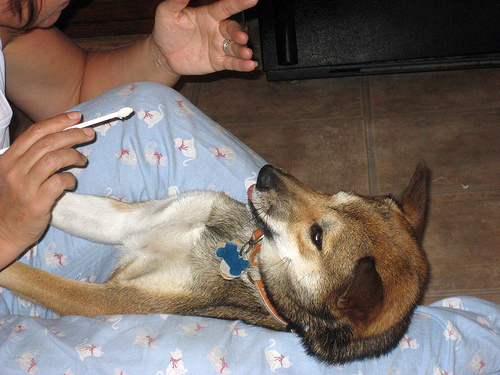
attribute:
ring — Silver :
[216, 40, 232, 57]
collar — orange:
[221, 214, 299, 323]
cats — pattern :
[135, 104, 197, 179]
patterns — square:
[209, 57, 499, 279]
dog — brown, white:
[63, 152, 447, 363]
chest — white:
[113, 188, 236, 295]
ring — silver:
[223, 40, 233, 52]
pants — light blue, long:
[1, 83, 498, 372]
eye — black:
[308, 223, 324, 253]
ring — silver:
[215, 36, 238, 58]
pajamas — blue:
[0, 80, 494, 371]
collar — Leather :
[243, 248, 266, 312]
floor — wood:
[31, 6, 499, 308]